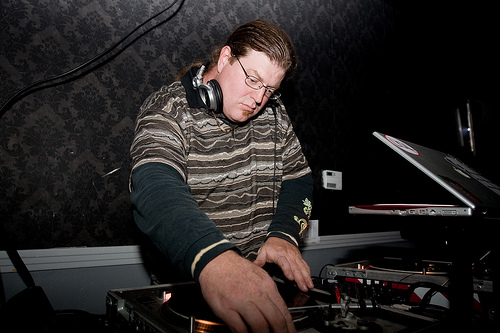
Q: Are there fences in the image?
A: No, there are no fences.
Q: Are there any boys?
A: No, there are no boys.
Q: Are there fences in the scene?
A: No, there are no fences.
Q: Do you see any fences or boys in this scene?
A: No, there are no fences or boys.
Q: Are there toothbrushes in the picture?
A: No, there are no toothbrushes.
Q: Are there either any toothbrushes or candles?
A: No, there are no toothbrushes or candles.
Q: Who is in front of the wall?
A: The man is in front of the wall.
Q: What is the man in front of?
A: The man is in front of the wall.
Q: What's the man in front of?
A: The man is in front of the wall.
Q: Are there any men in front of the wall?
A: Yes, there is a man in front of the wall.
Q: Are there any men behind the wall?
A: No, the man is in front of the wall.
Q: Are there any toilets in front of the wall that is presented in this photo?
A: No, there is a man in front of the wall.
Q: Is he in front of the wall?
A: Yes, the man is in front of the wall.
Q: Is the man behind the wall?
A: No, the man is in front of the wall.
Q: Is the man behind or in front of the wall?
A: The man is in front of the wall.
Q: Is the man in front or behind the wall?
A: The man is in front of the wall.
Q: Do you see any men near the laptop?
A: Yes, there is a man near the laptop.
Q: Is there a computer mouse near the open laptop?
A: No, there is a man near the laptop.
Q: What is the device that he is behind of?
A: The device is a laptop.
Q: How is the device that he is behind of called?
A: The device is a laptop.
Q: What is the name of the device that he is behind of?
A: The device is a laptop.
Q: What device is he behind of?
A: The man is behind the laptop.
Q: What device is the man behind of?
A: The man is behind the laptop.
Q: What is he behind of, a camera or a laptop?
A: The man is behind a laptop.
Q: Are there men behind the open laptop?
A: Yes, there is a man behind the laptop.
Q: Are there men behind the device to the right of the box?
A: Yes, there is a man behind the laptop.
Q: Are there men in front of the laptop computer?
A: No, the man is behind the laptop computer.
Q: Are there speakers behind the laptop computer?
A: No, there is a man behind the laptop computer.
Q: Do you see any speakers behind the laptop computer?
A: No, there is a man behind the laptop computer.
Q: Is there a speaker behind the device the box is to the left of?
A: No, there is a man behind the laptop computer.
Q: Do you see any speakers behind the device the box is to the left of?
A: No, there is a man behind the laptop computer.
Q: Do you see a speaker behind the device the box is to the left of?
A: No, there is a man behind the laptop computer.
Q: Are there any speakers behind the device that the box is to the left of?
A: No, there is a man behind the laptop computer.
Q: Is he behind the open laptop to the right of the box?
A: Yes, the man is behind the laptop.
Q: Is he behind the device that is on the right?
A: Yes, the man is behind the laptop.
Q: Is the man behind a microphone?
A: No, the man is behind the laptop.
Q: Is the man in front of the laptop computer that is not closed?
A: No, the man is behind the laptop.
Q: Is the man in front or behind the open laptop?
A: The man is behind the laptop.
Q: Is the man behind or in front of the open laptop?
A: The man is behind the laptop.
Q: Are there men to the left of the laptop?
A: Yes, there is a man to the left of the laptop.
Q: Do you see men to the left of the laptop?
A: Yes, there is a man to the left of the laptop.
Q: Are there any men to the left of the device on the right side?
A: Yes, there is a man to the left of the laptop.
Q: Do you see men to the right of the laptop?
A: No, the man is to the left of the laptop.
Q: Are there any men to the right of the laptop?
A: No, the man is to the left of the laptop.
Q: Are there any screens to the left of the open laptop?
A: No, there is a man to the left of the laptop.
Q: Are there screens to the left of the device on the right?
A: No, there is a man to the left of the laptop.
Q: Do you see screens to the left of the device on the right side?
A: No, there is a man to the left of the laptop.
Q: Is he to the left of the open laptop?
A: Yes, the man is to the left of the laptop.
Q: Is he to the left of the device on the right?
A: Yes, the man is to the left of the laptop.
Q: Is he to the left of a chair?
A: No, the man is to the left of the laptop.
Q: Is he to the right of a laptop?
A: No, the man is to the left of a laptop.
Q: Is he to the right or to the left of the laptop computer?
A: The man is to the left of the laptop computer.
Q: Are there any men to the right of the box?
A: No, the man is to the left of the box.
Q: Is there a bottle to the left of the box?
A: No, there is a man to the left of the box.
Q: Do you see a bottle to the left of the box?
A: No, there is a man to the left of the box.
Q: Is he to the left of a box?
A: Yes, the man is to the left of a box.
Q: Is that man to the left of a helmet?
A: No, the man is to the left of a box.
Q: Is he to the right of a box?
A: No, the man is to the left of a box.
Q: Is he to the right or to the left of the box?
A: The man is to the left of the box.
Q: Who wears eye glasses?
A: The man wears eye glasses.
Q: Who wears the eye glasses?
A: The man wears eye glasses.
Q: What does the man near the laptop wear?
A: The man wears eye glasses.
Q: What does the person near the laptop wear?
A: The man wears eye glasses.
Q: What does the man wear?
A: The man wears eye glasses.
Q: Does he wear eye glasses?
A: Yes, the man wears eye glasses.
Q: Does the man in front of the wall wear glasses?
A: No, the man wears eye glasses.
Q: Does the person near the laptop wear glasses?
A: No, the man wears eye glasses.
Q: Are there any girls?
A: No, there are no girls.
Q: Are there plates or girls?
A: No, there are no girls or plates.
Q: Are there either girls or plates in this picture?
A: No, there are no girls or plates.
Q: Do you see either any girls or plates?
A: No, there are no girls or plates.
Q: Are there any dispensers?
A: No, there are no dispensers.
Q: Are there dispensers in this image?
A: No, there are no dispensers.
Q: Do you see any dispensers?
A: No, there are no dispensers.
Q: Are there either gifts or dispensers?
A: No, there are no dispensers or gifts.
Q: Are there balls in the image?
A: No, there are no balls.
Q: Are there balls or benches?
A: No, there are no balls or benches.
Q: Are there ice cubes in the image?
A: No, there are no ice cubes.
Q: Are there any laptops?
A: Yes, there is a laptop.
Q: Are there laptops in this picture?
A: Yes, there is a laptop.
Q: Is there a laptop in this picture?
A: Yes, there is a laptop.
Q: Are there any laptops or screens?
A: Yes, there is a laptop.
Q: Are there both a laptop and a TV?
A: No, there is a laptop but no televisions.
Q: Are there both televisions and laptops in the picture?
A: No, there is a laptop but no televisions.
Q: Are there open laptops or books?
A: Yes, there is an open laptop.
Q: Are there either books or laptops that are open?
A: Yes, the laptop is open.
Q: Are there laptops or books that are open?
A: Yes, the laptop is open.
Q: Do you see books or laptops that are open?
A: Yes, the laptop is open.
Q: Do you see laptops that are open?
A: Yes, there is an open laptop.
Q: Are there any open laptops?
A: Yes, there is an open laptop.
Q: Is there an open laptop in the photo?
A: Yes, there is an open laptop.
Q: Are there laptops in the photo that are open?
A: Yes, there is a laptop that is open.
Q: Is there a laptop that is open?
A: Yes, there is a laptop that is open.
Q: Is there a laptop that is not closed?
A: Yes, there is a open laptop.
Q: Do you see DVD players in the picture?
A: No, there are no DVD players.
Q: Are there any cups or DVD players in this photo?
A: No, there are no DVD players or cups.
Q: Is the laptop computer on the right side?
A: Yes, the laptop computer is on the right of the image.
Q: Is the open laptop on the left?
A: No, the laptop is on the right of the image.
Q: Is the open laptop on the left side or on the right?
A: The laptop is on the right of the image.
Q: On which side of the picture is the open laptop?
A: The laptop is on the right of the image.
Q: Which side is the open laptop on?
A: The laptop is on the right of the image.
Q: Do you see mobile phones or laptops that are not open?
A: No, there is a laptop but it is open.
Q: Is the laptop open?
A: Yes, the laptop is open.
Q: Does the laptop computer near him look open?
A: Yes, the laptop is open.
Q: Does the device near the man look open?
A: Yes, the laptop is open.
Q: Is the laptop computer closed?
A: No, the laptop computer is open.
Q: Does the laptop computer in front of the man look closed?
A: No, the laptop computer is open.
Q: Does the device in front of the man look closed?
A: No, the laptop computer is open.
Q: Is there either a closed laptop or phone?
A: No, there is a laptop but it is open.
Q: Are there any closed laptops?
A: No, there is a laptop but it is open.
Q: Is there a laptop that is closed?
A: No, there is a laptop but it is open.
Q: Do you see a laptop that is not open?
A: No, there is a laptop but it is open.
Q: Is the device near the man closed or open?
A: The laptop is open.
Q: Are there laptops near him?
A: Yes, there is a laptop near the man.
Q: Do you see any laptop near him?
A: Yes, there is a laptop near the man.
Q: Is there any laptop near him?
A: Yes, there is a laptop near the man.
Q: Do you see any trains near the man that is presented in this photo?
A: No, there is a laptop near the man.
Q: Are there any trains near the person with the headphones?
A: No, there is a laptop near the man.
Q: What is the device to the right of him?
A: The device is a laptop.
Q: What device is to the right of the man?
A: The device is a laptop.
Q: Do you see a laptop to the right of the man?
A: Yes, there is a laptop to the right of the man.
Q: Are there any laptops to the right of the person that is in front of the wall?
A: Yes, there is a laptop to the right of the man.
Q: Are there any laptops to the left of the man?
A: No, the laptop is to the right of the man.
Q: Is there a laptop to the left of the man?
A: No, the laptop is to the right of the man.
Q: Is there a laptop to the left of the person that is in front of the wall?
A: No, the laptop is to the right of the man.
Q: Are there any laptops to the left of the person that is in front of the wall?
A: No, the laptop is to the right of the man.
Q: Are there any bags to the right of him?
A: No, there is a laptop to the right of the man.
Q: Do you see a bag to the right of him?
A: No, there is a laptop to the right of the man.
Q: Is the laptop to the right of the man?
A: Yes, the laptop is to the right of the man.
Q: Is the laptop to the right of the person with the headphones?
A: Yes, the laptop is to the right of the man.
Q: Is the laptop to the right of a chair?
A: No, the laptop is to the right of the man.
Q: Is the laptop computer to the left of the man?
A: No, the laptop computer is to the right of the man.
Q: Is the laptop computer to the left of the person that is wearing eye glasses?
A: No, the laptop computer is to the right of the man.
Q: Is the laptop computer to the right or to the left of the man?
A: The laptop computer is to the right of the man.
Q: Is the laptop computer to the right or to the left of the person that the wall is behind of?
A: The laptop computer is to the right of the man.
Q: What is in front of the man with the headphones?
A: The laptop is in front of the man.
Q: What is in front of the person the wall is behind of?
A: The laptop is in front of the man.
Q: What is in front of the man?
A: The laptop is in front of the man.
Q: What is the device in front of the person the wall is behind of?
A: The device is a laptop.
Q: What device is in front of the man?
A: The device is a laptop.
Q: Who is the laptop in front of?
A: The laptop is in front of the man.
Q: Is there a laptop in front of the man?
A: Yes, there is a laptop in front of the man.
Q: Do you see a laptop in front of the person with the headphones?
A: Yes, there is a laptop in front of the man.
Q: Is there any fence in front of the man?
A: No, there is a laptop in front of the man.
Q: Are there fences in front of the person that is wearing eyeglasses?
A: No, there is a laptop in front of the man.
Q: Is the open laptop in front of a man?
A: Yes, the laptop computer is in front of a man.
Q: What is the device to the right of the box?
A: The device is a laptop.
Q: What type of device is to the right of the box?
A: The device is a laptop.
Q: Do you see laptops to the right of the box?
A: Yes, there is a laptop to the right of the box.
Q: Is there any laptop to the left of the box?
A: No, the laptop is to the right of the box.